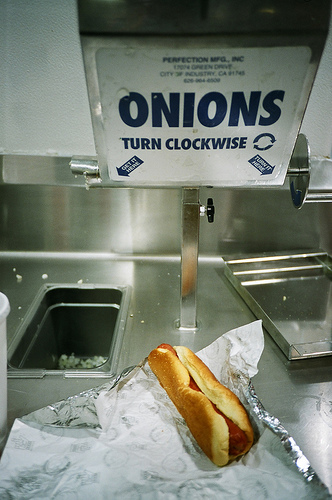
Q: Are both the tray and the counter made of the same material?
A: No, the tray is made of plastic and the counter is made of metal.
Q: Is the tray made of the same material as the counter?
A: No, the tray is made of plastic and the counter is made of metal.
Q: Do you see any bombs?
A: No, there are no bombs.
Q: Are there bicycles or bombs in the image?
A: No, there are no bombs or bicycles.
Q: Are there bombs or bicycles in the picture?
A: No, there are no bombs or bicycles.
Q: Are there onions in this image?
A: Yes, there are onions.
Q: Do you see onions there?
A: Yes, there are onions.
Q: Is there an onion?
A: Yes, there are onions.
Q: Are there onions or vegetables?
A: Yes, there are onions.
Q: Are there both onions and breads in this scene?
A: Yes, there are both onions and a bread.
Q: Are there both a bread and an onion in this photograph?
A: Yes, there are both an onion and a bread.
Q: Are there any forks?
A: No, there are no forks.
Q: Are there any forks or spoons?
A: No, there are no forks or spoons.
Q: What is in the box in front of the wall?
A: The onions are in the box.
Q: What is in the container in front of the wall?
A: The onions are in the box.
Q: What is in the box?
A: The onions are in the box.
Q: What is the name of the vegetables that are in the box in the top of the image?
A: The vegetables are onions.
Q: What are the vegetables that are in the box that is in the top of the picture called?
A: The vegetables are onions.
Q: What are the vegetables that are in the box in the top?
A: The vegetables are onions.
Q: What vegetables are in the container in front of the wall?
A: The vegetables are onions.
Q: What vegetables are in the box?
A: The vegetables are onions.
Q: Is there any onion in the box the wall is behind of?
A: Yes, there are onions in the box.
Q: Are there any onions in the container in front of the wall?
A: Yes, there are onions in the box.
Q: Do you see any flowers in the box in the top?
A: No, there are onions in the box.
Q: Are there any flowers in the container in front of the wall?
A: No, there are onions in the box.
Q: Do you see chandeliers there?
A: No, there are no chandeliers.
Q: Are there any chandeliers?
A: No, there are no chandeliers.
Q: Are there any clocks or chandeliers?
A: No, there are no chandeliers or clocks.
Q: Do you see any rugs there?
A: No, there are no rugs.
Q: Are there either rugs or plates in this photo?
A: No, there are no rugs or plates.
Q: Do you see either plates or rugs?
A: No, there are no rugs or plates.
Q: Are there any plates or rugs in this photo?
A: No, there are no rugs or plates.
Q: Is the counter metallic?
A: Yes, the counter is metallic.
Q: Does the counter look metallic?
A: Yes, the counter is metallic.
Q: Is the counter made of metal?
A: Yes, the counter is made of metal.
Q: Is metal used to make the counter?
A: Yes, the counter is made of metal.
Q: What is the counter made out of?
A: The counter is made of metal.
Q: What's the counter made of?
A: The counter is made of metal.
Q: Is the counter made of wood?
A: No, the counter is made of metal.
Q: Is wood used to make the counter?
A: No, the counter is made of metal.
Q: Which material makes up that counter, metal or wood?
A: The counter is made of metal.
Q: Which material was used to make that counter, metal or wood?
A: The counter is made of metal.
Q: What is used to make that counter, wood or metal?
A: The counter is made of metal.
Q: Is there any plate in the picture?
A: No, there are no plates.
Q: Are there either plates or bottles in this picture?
A: No, there are no plates or bottles.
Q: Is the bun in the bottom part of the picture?
A: Yes, the bun is in the bottom of the image.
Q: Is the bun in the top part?
A: No, the bun is in the bottom of the image.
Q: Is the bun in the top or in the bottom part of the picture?
A: The bun is in the bottom of the image.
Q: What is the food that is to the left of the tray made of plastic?
A: The food is a bun.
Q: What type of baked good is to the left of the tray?
A: The food is a bun.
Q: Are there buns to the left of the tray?
A: Yes, there is a bun to the left of the tray.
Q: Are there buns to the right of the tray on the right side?
A: No, the bun is to the left of the tray.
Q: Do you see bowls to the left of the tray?
A: No, there is a bun to the left of the tray.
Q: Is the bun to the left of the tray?
A: Yes, the bun is to the left of the tray.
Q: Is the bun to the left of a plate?
A: No, the bun is to the left of the tray.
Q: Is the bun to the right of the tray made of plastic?
A: No, the bun is to the left of the tray.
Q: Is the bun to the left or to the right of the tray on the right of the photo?
A: The bun is to the left of the tray.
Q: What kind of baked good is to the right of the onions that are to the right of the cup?
A: The food is a bun.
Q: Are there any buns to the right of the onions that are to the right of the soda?
A: Yes, there is a bun to the right of the onions.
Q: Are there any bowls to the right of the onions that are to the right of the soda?
A: No, there is a bun to the right of the onions.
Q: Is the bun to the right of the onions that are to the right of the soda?
A: Yes, the bun is to the right of the onions.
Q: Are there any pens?
A: No, there are no pens.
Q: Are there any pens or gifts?
A: No, there are no pens or gifts.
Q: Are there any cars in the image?
A: No, there are no cars.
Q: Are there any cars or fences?
A: No, there are no cars or fences.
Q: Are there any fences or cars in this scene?
A: No, there are no cars or fences.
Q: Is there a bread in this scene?
A: Yes, there is a bread.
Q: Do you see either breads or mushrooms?
A: Yes, there is a bread.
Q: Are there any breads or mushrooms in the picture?
A: Yes, there is a bread.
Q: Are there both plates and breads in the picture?
A: No, there is a bread but no plates.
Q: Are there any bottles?
A: No, there are no bottles.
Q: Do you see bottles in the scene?
A: No, there are no bottles.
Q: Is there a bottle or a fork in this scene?
A: No, there are no bottles or forks.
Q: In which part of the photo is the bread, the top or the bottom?
A: The bread is in the bottom of the image.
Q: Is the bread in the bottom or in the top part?
A: The bread is in the bottom of the image.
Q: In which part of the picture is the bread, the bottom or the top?
A: The bread is in the bottom of the image.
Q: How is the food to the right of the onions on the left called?
A: The food is a bread.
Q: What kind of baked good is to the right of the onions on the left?
A: The food is a bread.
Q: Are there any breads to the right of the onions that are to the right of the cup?
A: Yes, there is a bread to the right of the onions.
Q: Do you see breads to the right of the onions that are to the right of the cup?
A: Yes, there is a bread to the right of the onions.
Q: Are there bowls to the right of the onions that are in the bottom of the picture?
A: No, there is a bread to the right of the onions.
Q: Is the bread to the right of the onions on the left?
A: Yes, the bread is to the right of the onions.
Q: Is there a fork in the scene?
A: No, there are no forks.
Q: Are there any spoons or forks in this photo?
A: No, there are no forks or spoons.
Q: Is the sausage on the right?
A: Yes, the sausage is on the right of the image.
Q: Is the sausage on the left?
A: No, the sausage is on the right of the image.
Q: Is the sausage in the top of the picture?
A: No, the sausage is in the bottom of the image.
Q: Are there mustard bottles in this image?
A: No, there are no mustard bottles.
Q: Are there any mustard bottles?
A: No, there are no mustard bottles.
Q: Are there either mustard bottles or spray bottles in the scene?
A: No, there are no mustard bottles or spray bottles.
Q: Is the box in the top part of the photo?
A: Yes, the box is in the top of the image.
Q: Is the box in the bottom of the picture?
A: No, the box is in the top of the image.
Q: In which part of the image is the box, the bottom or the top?
A: The box is in the top of the image.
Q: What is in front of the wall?
A: The box is in front of the wall.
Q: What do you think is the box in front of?
A: The box is in front of the wall.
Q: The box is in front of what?
A: The box is in front of the wall.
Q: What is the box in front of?
A: The box is in front of the wall.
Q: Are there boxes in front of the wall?
A: Yes, there is a box in front of the wall.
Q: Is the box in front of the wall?
A: Yes, the box is in front of the wall.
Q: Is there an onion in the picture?
A: Yes, there are onions.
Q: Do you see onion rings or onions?
A: Yes, there are onions.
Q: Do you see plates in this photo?
A: No, there are no plates.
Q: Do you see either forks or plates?
A: No, there are no plates or forks.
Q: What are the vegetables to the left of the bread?
A: The vegetables are onions.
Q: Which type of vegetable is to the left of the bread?
A: The vegetables are onions.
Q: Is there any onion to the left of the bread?
A: Yes, there are onions to the left of the bread.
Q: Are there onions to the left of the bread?
A: Yes, there are onions to the left of the bread.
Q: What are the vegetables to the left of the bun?
A: The vegetables are onions.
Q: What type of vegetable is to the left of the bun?
A: The vegetables are onions.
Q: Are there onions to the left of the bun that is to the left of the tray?
A: Yes, there are onions to the left of the bun.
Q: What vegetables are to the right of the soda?
A: The vegetables are onions.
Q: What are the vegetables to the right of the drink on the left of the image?
A: The vegetables are onions.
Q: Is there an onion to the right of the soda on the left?
A: Yes, there are onions to the right of the soda.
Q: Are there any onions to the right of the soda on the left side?
A: Yes, there are onions to the right of the soda.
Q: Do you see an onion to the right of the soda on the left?
A: Yes, there are onions to the right of the soda.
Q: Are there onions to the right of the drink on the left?
A: Yes, there are onions to the right of the soda.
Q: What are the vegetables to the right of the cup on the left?
A: The vegetables are onions.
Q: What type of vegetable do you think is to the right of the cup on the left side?
A: The vegetables are onions.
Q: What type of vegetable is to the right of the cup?
A: The vegetables are onions.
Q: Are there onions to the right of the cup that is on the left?
A: Yes, there are onions to the right of the cup.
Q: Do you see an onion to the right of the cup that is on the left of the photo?
A: Yes, there are onions to the right of the cup.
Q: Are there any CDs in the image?
A: No, there are no cds.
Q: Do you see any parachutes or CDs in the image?
A: No, there are no CDs or parachutes.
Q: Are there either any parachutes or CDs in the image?
A: No, there are no CDs or parachutes.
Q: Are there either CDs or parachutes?
A: No, there are no CDs or parachutes.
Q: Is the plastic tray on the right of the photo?
A: Yes, the tray is on the right of the image.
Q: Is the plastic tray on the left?
A: No, the tray is on the right of the image.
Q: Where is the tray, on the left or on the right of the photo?
A: The tray is on the right of the image.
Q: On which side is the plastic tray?
A: The tray is on the right of the image.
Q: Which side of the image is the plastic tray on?
A: The tray is on the right of the image.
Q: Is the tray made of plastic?
A: Yes, the tray is made of plastic.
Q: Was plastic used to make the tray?
A: Yes, the tray is made of plastic.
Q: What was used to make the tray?
A: The tray is made of plastic.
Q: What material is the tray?
A: The tray is made of plastic.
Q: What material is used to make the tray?
A: The tray is made of plastic.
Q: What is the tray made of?
A: The tray is made of plastic.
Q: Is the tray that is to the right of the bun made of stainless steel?
A: No, the tray is made of plastic.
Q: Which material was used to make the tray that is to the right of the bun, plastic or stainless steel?
A: The tray is made of plastic.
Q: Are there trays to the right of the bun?
A: Yes, there is a tray to the right of the bun.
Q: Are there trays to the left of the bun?
A: No, the tray is to the right of the bun.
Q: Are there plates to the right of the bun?
A: No, there is a tray to the right of the bun.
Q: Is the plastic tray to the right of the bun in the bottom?
A: Yes, the tray is to the right of the bun.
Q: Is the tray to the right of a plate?
A: No, the tray is to the right of the bun.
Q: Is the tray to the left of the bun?
A: No, the tray is to the right of the bun.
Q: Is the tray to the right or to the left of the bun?
A: The tray is to the right of the bun.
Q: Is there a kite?
A: No, there are no kites.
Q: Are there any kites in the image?
A: No, there are no kites.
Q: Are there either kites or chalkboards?
A: No, there are no kites or chalkboards.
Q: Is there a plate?
A: No, there are no plates.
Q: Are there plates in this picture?
A: No, there are no plates.